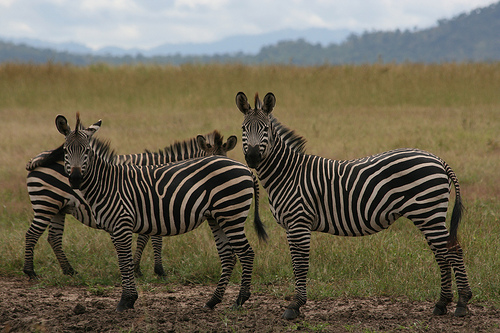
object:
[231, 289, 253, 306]
zebras hooves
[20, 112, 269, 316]
two zebras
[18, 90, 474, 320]
three zebras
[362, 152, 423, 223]
striped pattern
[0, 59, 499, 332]
field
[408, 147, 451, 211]
end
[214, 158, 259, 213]
end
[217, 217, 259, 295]
leg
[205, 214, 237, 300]
leg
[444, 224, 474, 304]
leg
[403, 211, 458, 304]
leg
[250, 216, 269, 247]
tuft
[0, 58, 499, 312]
grassland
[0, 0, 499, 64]
mountains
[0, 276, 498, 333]
dirt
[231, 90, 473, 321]
zebra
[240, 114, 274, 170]
face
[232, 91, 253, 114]
ears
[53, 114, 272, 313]
zebra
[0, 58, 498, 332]
plain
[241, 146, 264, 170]
nose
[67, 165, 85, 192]
nose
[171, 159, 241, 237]
stripe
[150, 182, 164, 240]
stripe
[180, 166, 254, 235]
stripe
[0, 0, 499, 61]
hillside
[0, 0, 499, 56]
sky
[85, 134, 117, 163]
mane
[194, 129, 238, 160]
zebra head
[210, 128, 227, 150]
hair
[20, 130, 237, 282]
zebra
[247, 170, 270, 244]
tail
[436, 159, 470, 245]
tail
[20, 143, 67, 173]
tail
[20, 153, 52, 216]
behind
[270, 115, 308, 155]
hair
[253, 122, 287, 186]
neck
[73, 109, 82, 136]
hair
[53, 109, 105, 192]
head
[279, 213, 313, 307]
leg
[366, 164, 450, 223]
stripe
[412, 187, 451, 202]
stripe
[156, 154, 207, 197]
stripe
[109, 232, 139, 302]
leg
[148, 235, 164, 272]
leg